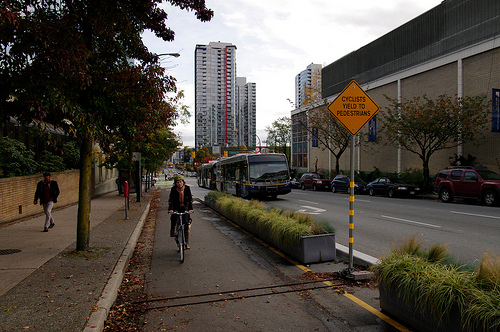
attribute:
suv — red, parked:
[430, 163, 499, 210]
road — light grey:
[170, 167, 500, 277]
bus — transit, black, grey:
[215, 150, 294, 202]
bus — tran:
[192, 158, 216, 191]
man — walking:
[31, 169, 62, 233]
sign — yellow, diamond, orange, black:
[327, 77, 384, 136]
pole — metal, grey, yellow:
[348, 132, 357, 276]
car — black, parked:
[363, 172, 421, 199]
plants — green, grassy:
[202, 187, 335, 243]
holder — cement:
[204, 194, 339, 268]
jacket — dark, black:
[33, 178, 60, 206]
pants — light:
[36, 195, 57, 227]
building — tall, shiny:
[190, 38, 261, 156]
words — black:
[335, 94, 375, 120]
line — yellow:
[201, 200, 415, 331]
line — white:
[383, 212, 444, 231]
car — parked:
[328, 172, 369, 194]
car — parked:
[300, 169, 330, 192]